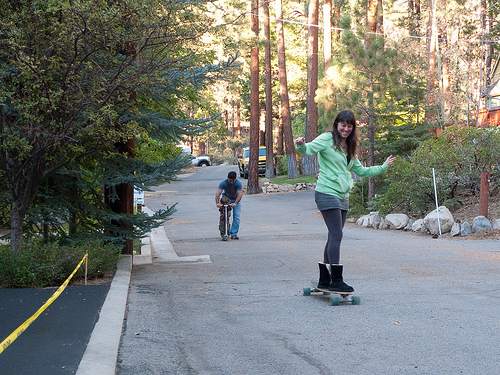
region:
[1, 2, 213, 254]
a big tree on the side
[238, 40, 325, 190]
a group of long narrow tree trunks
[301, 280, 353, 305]
a long black skateboard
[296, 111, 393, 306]
a woman riding a skateboard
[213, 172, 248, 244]
a man and a kid riding a scooter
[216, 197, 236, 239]
a kid on a scooter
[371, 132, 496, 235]
a little green bush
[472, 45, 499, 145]
a house on the side of the road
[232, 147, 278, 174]
a red truck parked on the side of the road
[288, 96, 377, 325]
lady is skating in the road.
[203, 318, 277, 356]
road is grey in color.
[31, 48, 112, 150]
trees are green in color.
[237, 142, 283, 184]
yellow car is parked in the road side.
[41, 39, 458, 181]
trees are lined up on both sides of the road.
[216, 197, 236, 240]
boy is driving the scooter.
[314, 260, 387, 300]
lady wears black shoes.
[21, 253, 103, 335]
yellow rope is tied to the sides of the road.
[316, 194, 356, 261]
lady pant is grey in color.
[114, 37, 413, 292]
daytime picture.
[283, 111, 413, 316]
Girl riding on skateboard.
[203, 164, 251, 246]
Boy riding on scooter.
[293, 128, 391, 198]
Girl wearing green jacket.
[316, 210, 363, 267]
Girl wearing gray leggings.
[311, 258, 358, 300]
Girl wearing black boots.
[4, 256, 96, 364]
Yellow tape stretched across driveway.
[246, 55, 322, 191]
Trunks of pine trees growing next to road.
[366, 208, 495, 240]
Huge rocks lined along road.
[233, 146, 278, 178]
Yellow truck parked on side of road.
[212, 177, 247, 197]
Boy wearing blue shirt.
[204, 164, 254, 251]
a man helping a child ride a kick scooter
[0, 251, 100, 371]
yellow caution tape across a driveway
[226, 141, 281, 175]
a yellow truck parked on the block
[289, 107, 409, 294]
a dark haired woman smiling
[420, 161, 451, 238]
a white driveway marker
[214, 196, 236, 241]
a young child on a scooter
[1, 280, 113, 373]
a freshly paved driveway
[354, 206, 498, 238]
a set of rocks lining a driveway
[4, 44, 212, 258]
a tree growing by the side of the street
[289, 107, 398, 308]
cute girl on a skateboard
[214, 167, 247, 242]
a hunched over man on a scooter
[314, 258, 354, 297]
a pair of black boots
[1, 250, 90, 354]
a string of yellow tape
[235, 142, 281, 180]
a yellow truck in the back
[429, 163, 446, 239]
a white post sticking out of the ground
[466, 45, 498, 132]
a brown house and a brown fence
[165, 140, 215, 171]
a white colored truck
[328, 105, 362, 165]
long hair of a woman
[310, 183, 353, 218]
a gray colored skirt